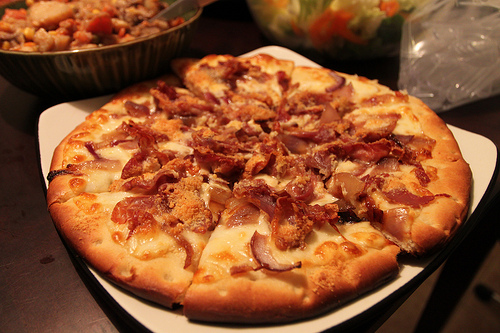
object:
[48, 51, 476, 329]
pizza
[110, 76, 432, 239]
top